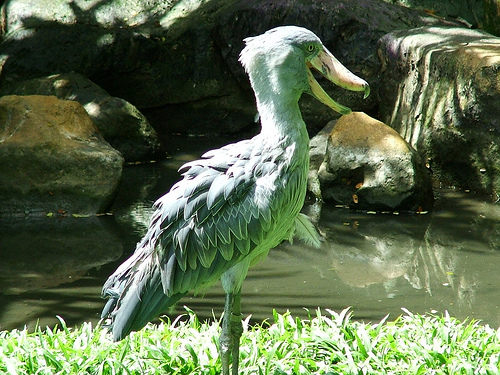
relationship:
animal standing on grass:
[101, 26, 370, 375] [21, 322, 476, 364]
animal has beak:
[101, 26, 370, 375] [306, 46, 370, 115]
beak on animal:
[306, 46, 370, 115] [101, 26, 370, 375]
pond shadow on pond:
[14, 0, 223, 295] [2, 95, 496, 330]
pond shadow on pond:
[0, 140, 500, 333] [2, 95, 496, 330]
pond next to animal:
[1, 132, 483, 326] [101, 26, 370, 375]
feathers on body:
[101, 142, 305, 343] [95, 127, 311, 343]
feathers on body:
[175, 160, 206, 172] [95, 127, 311, 343]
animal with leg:
[101, 26, 370, 375] [216, 292, 233, 374]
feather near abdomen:
[296, 212, 326, 253] [213, 187, 281, 268]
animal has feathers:
[101, 26, 370, 375] [192, 168, 300, 274]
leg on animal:
[219, 274, 244, 375] [101, 26, 370, 375]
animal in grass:
[82, 19, 380, 372] [27, 322, 443, 357]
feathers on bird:
[101, 142, 305, 343] [64, 12, 398, 360]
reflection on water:
[327, 221, 500, 298] [2, 217, 491, 323]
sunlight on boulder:
[3, 2, 201, 24] [306, 110, 424, 208]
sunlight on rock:
[3, 2, 201, 24] [2, 95, 124, 214]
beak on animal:
[306, 46, 370, 115] [82, 19, 380, 372]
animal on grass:
[101, 26, 370, 375] [2, 302, 498, 373]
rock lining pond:
[0, 95, 125, 219] [4, 194, 497, 334]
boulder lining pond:
[306, 110, 424, 208] [4, 194, 497, 334]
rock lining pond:
[377, 28, 500, 206] [4, 194, 497, 334]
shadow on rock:
[0, 0, 436, 113] [1, 2, 466, 138]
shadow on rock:
[110, 17, 134, 44] [1, 2, 466, 138]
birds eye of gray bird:
[303, 42, 315, 54] [98, 23, 371, 373]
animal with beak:
[101, 26, 370, 375] [307, 46, 369, 116]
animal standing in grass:
[101, 26, 370, 375] [0, 313, 497, 373]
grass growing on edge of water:
[0, 313, 497, 373] [3, 199, 498, 319]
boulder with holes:
[279, 97, 434, 224] [342, 169, 367, 188]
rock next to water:
[7, 85, 125, 222] [3, 199, 498, 319]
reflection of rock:
[327, 221, 500, 298] [299, 105, 422, 220]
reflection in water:
[327, 221, 500, 298] [0, 121, 497, 332]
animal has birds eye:
[101, 26, 370, 375] [303, 42, 315, 54]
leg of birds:
[219, 274, 244, 375] [101, 22, 371, 372]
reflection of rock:
[336, 221, 448, 292] [297, 111, 427, 220]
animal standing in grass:
[101, 26, 370, 375] [2, 302, 498, 373]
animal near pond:
[101, 26, 370, 375] [1, 132, 483, 326]